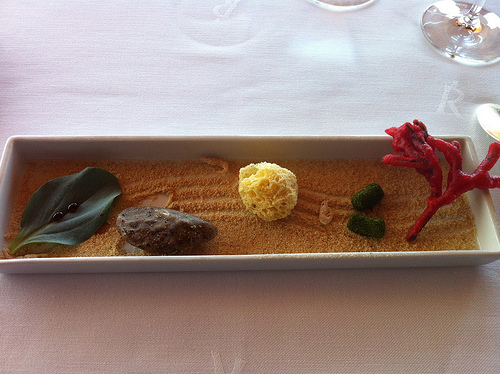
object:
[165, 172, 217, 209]
dirt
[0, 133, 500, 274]
tray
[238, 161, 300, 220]
sponge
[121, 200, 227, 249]
rock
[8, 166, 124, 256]
leaf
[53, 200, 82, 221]
charcoal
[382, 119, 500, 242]
coral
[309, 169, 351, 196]
sand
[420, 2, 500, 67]
glass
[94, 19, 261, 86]
cloth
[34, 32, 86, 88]
tag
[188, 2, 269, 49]
plate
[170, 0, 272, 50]
indentation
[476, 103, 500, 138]
sugar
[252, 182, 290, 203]
yellow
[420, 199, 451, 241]
stem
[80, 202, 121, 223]
beans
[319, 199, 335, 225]
stone